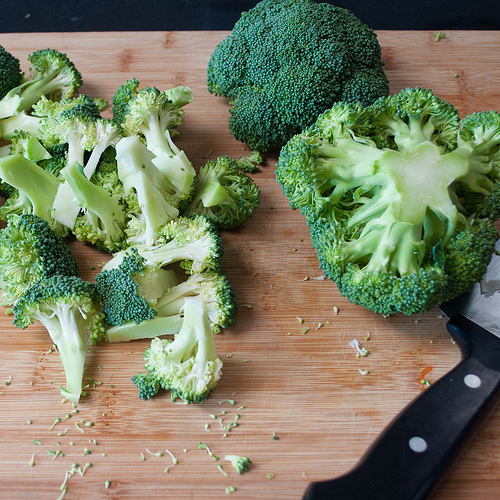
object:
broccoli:
[181, 152, 262, 234]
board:
[1, 33, 498, 499]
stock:
[376, 138, 471, 227]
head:
[204, 2, 388, 161]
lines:
[259, 383, 407, 396]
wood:
[18, 38, 458, 499]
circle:
[405, 435, 427, 455]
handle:
[300, 315, 499, 500]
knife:
[295, 214, 499, 499]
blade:
[437, 241, 498, 308]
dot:
[461, 372, 481, 390]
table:
[0, 0, 499, 34]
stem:
[41, 322, 97, 406]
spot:
[247, 294, 380, 397]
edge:
[0, 26, 499, 35]